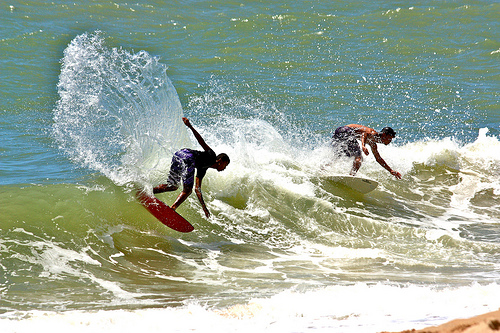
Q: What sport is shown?
A: Surfing.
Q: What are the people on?
A: Surfboards.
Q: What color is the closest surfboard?
A: Red.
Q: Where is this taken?
A: Beach.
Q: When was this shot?
A: Daytime.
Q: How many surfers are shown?
A: 2.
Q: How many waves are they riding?
A: 1.